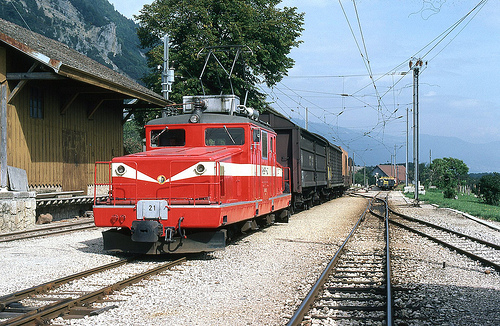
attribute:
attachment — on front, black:
[128, 217, 160, 245]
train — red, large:
[91, 87, 356, 246]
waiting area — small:
[0, 1, 172, 220]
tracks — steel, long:
[346, 189, 498, 271]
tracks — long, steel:
[284, 188, 391, 322]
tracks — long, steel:
[1, 255, 183, 324]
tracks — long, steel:
[1, 217, 96, 244]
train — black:
[283, 118, 335, 182]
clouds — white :
[363, 29, 493, 56]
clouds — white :
[332, 50, 480, 122]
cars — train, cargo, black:
[276, 136, 335, 196]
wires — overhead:
[331, 1, 496, 146]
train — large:
[87, 85, 359, 260]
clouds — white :
[251, 37, 498, 123]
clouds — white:
[315, 39, 350, 61]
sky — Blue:
[375, 9, 424, 52]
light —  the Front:
[192, 161, 208, 175]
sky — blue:
[316, 13, 491, 148]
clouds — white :
[295, 80, 355, 125]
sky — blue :
[312, 0, 496, 155]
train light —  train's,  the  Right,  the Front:
[114, 162, 126, 174]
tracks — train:
[311, 261, 406, 321]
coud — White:
[346, 71, 425, 88]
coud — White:
[423, 84, 498, 121]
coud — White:
[275, 49, 327, 99]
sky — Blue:
[108, 0, 497, 172]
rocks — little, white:
[148, 277, 192, 305]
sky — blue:
[136, 0, 498, 163]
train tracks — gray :
[297, 190, 498, 322]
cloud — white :
[369, 70, 408, 80]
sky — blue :
[296, 0, 493, 110]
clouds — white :
[313, 15, 351, 70]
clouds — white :
[305, 51, 410, 93]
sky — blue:
[290, 59, 492, 148]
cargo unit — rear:
[267, 120, 355, 207]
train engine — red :
[115, 107, 355, 267]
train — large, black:
[65, 57, 380, 281]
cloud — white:
[335, 58, 424, 104]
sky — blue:
[242, 0, 496, 124]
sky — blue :
[438, 95, 450, 108]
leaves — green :
[151, 5, 277, 97]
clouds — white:
[337, 98, 384, 148]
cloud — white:
[352, 63, 427, 94]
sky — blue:
[113, 2, 498, 152]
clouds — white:
[332, 57, 427, 114]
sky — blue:
[116, 0, 494, 190]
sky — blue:
[391, 20, 404, 42]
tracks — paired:
[278, 186, 420, 324]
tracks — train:
[420, 216, 483, 261]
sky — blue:
[311, 11, 482, 139]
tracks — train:
[1, 251, 233, 323]